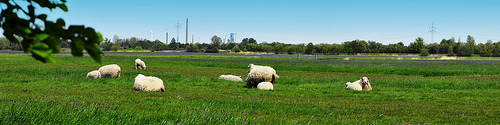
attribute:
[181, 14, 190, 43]
utility pole — electric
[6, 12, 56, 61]
leaves — green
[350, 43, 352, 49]
leaves — green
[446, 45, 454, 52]
leaves — green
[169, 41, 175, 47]
leaves — green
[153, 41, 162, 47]
leaves — green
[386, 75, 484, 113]
grass — trimmed